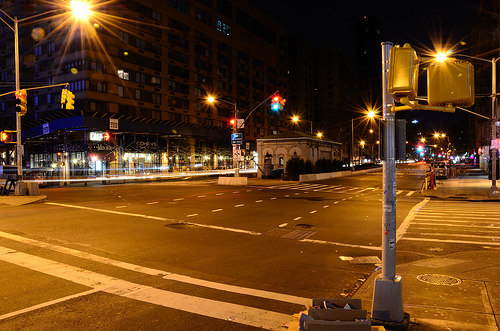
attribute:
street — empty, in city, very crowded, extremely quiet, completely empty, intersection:
[0, 156, 499, 327]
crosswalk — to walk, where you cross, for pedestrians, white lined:
[146, 172, 420, 205]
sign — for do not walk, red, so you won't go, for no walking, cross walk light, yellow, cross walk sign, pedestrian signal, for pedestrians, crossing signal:
[3, 132, 13, 142]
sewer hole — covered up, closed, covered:
[168, 220, 197, 231]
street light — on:
[3, 2, 112, 197]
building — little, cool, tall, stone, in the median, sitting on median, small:
[254, 127, 343, 180]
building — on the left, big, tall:
[2, 2, 318, 173]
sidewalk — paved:
[427, 154, 500, 201]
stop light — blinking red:
[228, 116, 240, 136]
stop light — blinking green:
[269, 92, 282, 112]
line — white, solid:
[43, 196, 386, 267]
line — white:
[1, 227, 307, 325]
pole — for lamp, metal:
[232, 101, 243, 175]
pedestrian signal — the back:
[59, 86, 70, 107]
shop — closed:
[28, 141, 257, 172]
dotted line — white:
[270, 189, 366, 240]